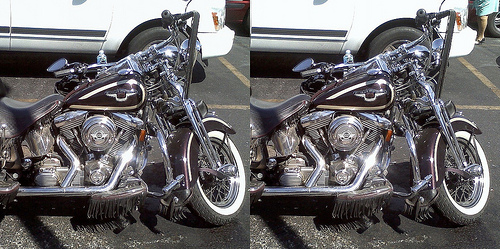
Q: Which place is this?
A: It is a pavement.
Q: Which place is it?
A: It is a pavement.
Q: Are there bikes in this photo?
A: Yes, there is a bike.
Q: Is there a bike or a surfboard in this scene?
A: Yes, there is a bike.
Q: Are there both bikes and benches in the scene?
A: No, there is a bike but no benches.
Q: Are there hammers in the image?
A: No, there are no hammers.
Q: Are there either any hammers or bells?
A: No, there are no hammers or bells.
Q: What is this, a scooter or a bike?
A: This is a bike.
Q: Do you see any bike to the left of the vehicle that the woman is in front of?
A: Yes, there is a bike to the left of the vehicle.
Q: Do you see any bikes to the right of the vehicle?
A: No, the bike is to the left of the vehicle.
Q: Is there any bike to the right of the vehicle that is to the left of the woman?
A: No, the bike is to the left of the vehicle.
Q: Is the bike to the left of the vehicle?
A: Yes, the bike is to the left of the vehicle.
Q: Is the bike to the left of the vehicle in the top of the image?
A: Yes, the bike is to the left of the vehicle.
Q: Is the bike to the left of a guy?
A: No, the bike is to the left of the vehicle.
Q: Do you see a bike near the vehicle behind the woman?
A: Yes, there is a bike near the vehicle.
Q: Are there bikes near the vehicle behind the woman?
A: Yes, there is a bike near the vehicle.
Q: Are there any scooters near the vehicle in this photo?
A: No, there is a bike near the vehicle.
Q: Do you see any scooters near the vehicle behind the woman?
A: No, there is a bike near the vehicle.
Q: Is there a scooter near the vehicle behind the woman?
A: No, there is a bike near the vehicle.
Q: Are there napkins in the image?
A: No, there are no napkins.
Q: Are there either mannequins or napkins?
A: No, there are no napkins or mannequins.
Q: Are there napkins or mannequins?
A: No, there are no napkins or mannequins.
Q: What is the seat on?
A: The seat is on the bike.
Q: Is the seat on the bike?
A: Yes, the seat is on the bike.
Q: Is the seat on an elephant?
A: No, the seat is on the bike.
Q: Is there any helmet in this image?
A: No, there are no helmets.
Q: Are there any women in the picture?
A: Yes, there is a woman.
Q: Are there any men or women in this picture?
A: Yes, there is a woman.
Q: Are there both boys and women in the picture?
A: No, there is a woman but no boys.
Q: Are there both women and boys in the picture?
A: No, there is a woman but no boys.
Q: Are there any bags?
A: No, there are no bags.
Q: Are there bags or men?
A: No, there are no bags or men.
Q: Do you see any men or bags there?
A: No, there are no bags or men.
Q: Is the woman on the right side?
A: Yes, the woman is on the right of the image.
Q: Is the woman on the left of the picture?
A: No, the woman is on the right of the image.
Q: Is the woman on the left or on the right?
A: The woman is on the right of the image.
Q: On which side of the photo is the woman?
A: The woman is on the right of the image.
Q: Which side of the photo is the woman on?
A: The woman is on the right of the image.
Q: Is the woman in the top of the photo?
A: Yes, the woman is in the top of the image.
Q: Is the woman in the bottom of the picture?
A: No, the woman is in the top of the image.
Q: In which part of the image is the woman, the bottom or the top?
A: The woman is in the top of the image.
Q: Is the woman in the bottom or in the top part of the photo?
A: The woman is in the top of the image.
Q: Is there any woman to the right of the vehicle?
A: Yes, there is a woman to the right of the vehicle.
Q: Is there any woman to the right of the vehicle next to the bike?
A: Yes, there is a woman to the right of the vehicle.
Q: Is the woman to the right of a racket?
A: No, the woman is to the right of the vehicle.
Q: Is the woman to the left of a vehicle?
A: No, the woman is to the right of a vehicle.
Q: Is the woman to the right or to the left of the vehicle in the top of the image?
A: The woman is to the right of the vehicle.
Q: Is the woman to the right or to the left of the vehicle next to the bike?
A: The woman is to the right of the vehicle.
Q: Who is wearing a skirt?
A: The woman is wearing a skirt.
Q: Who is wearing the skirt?
A: The woman is wearing a skirt.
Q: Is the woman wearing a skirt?
A: Yes, the woman is wearing a skirt.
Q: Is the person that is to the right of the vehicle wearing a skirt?
A: Yes, the woman is wearing a skirt.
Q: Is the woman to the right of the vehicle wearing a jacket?
A: No, the woman is wearing a skirt.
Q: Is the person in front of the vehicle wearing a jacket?
A: No, the woman is wearing a skirt.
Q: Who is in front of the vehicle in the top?
A: The woman is in front of the vehicle.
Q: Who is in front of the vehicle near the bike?
A: The woman is in front of the vehicle.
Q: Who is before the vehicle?
A: The woman is in front of the vehicle.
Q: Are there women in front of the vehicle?
A: Yes, there is a woman in front of the vehicle.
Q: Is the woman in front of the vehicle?
A: Yes, the woman is in front of the vehicle.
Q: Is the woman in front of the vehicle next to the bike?
A: Yes, the woman is in front of the vehicle.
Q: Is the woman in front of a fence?
A: No, the woman is in front of the vehicle.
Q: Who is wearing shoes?
A: The woman is wearing shoes.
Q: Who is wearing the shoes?
A: The woman is wearing shoes.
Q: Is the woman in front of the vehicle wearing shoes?
A: Yes, the woman is wearing shoes.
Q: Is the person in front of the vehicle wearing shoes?
A: Yes, the woman is wearing shoes.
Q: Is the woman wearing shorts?
A: No, the woman is wearing shoes.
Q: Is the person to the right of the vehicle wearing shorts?
A: No, the woman is wearing shoes.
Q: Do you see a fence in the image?
A: No, there are no fences.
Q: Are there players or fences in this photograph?
A: No, there are no fences or players.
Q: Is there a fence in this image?
A: No, there are no fences.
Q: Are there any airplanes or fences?
A: No, there are no fences or airplanes.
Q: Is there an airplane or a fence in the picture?
A: No, there are no fences or airplanes.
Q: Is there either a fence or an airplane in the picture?
A: No, there are no fences or airplanes.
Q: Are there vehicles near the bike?
A: Yes, there is a vehicle near the bike.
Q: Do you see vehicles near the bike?
A: Yes, there is a vehicle near the bike.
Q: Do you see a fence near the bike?
A: No, there is a vehicle near the bike.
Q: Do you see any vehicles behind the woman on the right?
A: Yes, there is a vehicle behind the woman.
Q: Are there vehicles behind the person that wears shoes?
A: Yes, there is a vehicle behind the woman.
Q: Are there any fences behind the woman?
A: No, there is a vehicle behind the woman.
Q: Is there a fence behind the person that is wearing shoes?
A: No, there is a vehicle behind the woman.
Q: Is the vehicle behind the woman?
A: Yes, the vehicle is behind the woman.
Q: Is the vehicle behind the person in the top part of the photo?
A: Yes, the vehicle is behind the woman.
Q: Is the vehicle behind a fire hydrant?
A: No, the vehicle is behind the woman.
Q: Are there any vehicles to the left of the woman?
A: Yes, there is a vehicle to the left of the woman.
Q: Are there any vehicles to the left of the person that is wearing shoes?
A: Yes, there is a vehicle to the left of the woman.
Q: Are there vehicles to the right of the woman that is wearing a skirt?
A: No, the vehicle is to the left of the woman.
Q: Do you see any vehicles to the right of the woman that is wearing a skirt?
A: No, the vehicle is to the left of the woman.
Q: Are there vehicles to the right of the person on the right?
A: No, the vehicle is to the left of the woman.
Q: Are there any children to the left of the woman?
A: No, there is a vehicle to the left of the woman.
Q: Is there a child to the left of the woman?
A: No, there is a vehicle to the left of the woman.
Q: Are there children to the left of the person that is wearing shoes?
A: No, there is a vehicle to the left of the woman.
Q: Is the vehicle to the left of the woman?
A: Yes, the vehicle is to the left of the woman.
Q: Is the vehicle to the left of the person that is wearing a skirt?
A: Yes, the vehicle is to the left of the woman.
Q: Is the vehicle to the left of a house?
A: No, the vehicle is to the left of the woman.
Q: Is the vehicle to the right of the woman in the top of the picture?
A: No, the vehicle is to the left of the woman.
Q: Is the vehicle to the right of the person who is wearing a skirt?
A: No, the vehicle is to the left of the woman.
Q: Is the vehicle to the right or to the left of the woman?
A: The vehicle is to the left of the woman.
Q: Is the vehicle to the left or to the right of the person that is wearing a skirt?
A: The vehicle is to the left of the woman.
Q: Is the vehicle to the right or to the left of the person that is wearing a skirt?
A: The vehicle is to the left of the woman.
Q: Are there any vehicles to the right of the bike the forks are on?
A: Yes, there is a vehicle to the right of the bike.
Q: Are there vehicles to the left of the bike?
A: No, the vehicle is to the right of the bike.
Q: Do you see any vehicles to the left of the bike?
A: No, the vehicle is to the right of the bike.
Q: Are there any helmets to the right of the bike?
A: No, there is a vehicle to the right of the bike.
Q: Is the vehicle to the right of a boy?
A: No, the vehicle is to the right of the bike.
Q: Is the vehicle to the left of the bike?
A: No, the vehicle is to the right of the bike.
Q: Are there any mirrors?
A: Yes, there is a mirror.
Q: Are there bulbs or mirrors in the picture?
A: Yes, there is a mirror.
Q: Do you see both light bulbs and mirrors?
A: No, there is a mirror but no light bulbs.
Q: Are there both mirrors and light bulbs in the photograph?
A: No, there is a mirror but no light bulbs.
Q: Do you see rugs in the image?
A: No, there are no rugs.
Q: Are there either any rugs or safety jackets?
A: No, there are no rugs or safety jackets.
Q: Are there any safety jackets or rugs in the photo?
A: No, there are no rugs or safety jackets.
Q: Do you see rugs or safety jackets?
A: No, there are no rugs or safety jackets.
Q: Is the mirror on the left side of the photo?
A: Yes, the mirror is on the left of the image.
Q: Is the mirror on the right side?
A: No, the mirror is on the left of the image.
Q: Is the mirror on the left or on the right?
A: The mirror is on the left of the image.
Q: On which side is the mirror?
A: The mirror is on the left of the image.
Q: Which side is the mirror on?
A: The mirror is on the left of the image.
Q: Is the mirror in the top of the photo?
A: Yes, the mirror is in the top of the image.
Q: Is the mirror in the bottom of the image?
A: No, the mirror is in the top of the image.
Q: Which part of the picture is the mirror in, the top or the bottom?
A: The mirror is in the top of the image.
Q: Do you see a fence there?
A: No, there are no fences.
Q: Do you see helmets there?
A: No, there are no helmets.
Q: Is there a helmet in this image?
A: No, there are no helmets.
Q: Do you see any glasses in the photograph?
A: No, there are no glasses.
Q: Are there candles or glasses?
A: No, there are no glasses or candles.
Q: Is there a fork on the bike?
A: Yes, there are forks on the bike.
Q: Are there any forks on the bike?
A: Yes, there are forks on the bike.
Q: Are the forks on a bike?
A: Yes, the forks are on a bike.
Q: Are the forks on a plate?
A: No, the forks are on a bike.